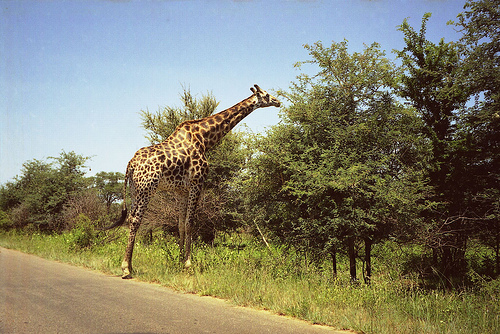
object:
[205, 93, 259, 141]
neck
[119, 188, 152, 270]
back legs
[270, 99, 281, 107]
mouth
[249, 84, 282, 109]
head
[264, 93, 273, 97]
eye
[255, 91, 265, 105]
ear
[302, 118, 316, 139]
leaves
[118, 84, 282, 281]
giraffe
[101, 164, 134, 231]
tail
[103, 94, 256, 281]
body